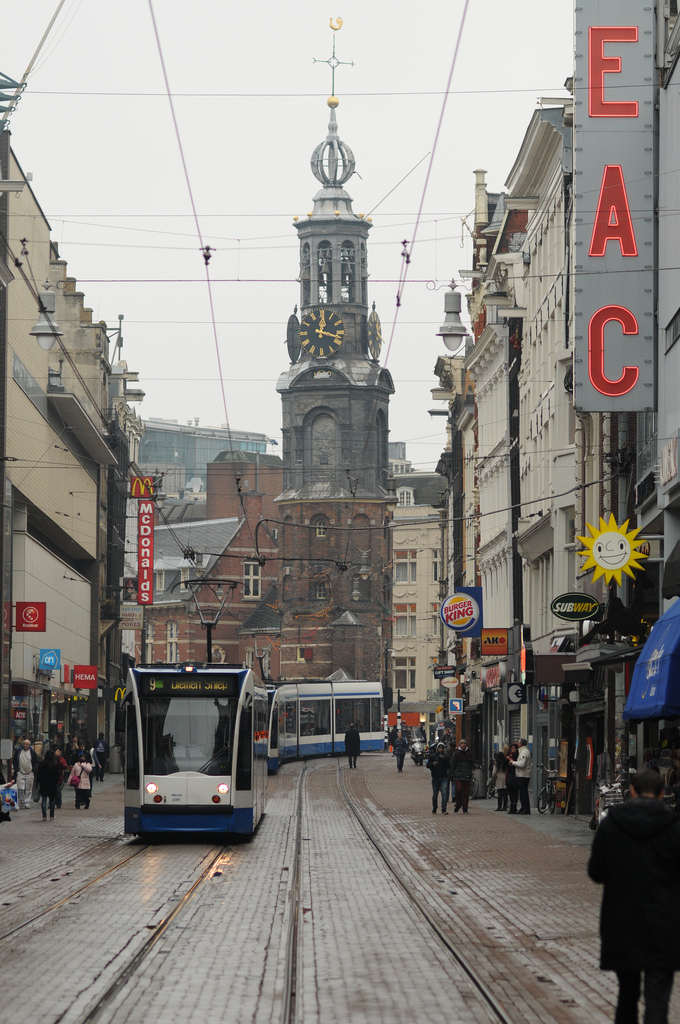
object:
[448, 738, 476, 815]
man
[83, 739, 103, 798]
woman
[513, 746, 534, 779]
coat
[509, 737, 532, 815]
man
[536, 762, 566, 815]
bike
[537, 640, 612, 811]
store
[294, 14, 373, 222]
steeple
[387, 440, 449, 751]
building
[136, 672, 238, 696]
board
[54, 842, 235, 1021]
track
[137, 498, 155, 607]
sign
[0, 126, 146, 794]
building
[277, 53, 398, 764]
building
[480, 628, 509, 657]
sign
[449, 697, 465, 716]
sign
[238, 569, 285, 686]
building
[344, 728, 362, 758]
jacket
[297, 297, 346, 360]
clock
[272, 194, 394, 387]
tower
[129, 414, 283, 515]
building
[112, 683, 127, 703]
sign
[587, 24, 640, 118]
letter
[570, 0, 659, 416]
sign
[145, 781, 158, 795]
headlights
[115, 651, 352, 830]
train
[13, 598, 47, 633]
sign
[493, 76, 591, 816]
building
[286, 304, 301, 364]
clocks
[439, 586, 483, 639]
sign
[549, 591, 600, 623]
sign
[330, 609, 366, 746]
building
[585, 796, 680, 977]
coat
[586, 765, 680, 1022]
man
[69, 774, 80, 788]
bag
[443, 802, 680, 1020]
walkway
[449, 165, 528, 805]
building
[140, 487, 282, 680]
building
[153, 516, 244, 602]
roof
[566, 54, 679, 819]
building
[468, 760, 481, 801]
bicycle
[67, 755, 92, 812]
woman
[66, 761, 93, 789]
coat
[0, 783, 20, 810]
bag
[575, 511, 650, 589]
sign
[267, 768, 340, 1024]
tracks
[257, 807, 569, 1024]
road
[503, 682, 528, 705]
sign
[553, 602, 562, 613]
letters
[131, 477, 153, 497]
symbol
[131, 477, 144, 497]
arches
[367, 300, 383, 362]
clock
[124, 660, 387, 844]
street car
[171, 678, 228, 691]
destination sign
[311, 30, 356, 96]
cross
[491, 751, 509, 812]
person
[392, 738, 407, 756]
jacket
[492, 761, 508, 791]
jacket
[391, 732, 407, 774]
person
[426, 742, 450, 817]
person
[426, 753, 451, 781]
jacket